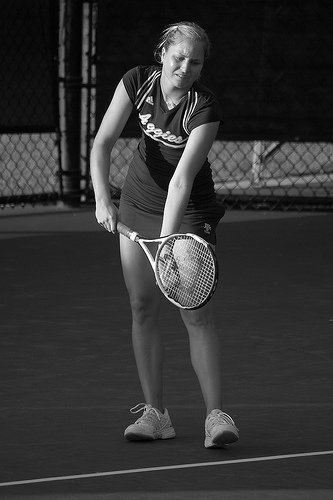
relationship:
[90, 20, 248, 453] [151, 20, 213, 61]
girl has light hair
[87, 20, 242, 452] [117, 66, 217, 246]
girl wearing dress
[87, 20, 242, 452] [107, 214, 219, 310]
girl has racket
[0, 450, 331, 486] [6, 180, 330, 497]
line on tennis court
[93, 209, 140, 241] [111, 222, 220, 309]
handle on racket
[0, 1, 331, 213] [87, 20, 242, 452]
fence behind girl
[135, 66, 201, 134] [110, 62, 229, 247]
stripes on dress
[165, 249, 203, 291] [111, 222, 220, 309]
logo on racket